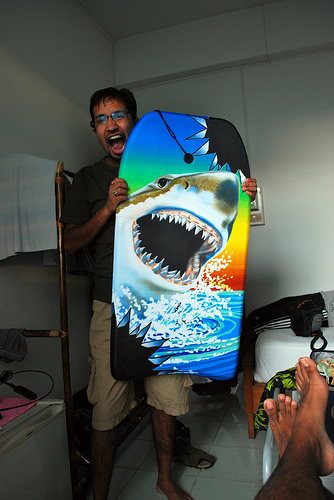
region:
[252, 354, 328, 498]
mans feet on the bed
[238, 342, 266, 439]
a brown bed post under the bed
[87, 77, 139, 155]
a man with glasses on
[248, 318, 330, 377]
a bed with with sheets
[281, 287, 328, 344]
a camera on the bed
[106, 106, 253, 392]
a board with a shark on it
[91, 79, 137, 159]
a man with his mouth open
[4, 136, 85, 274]
white cloth on the rack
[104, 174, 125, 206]
a man with a ring on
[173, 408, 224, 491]
brown sandals on the white floor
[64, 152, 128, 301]
the man is wearing a short sleeve shirt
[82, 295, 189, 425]
the man is wearing shorts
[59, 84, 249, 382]
the man is holding a surfboard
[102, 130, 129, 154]
the man has his mouth open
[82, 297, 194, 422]
the shorts are khaki in color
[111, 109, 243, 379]
the surfboard has a shark painted on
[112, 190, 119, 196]
the man is wearing a ring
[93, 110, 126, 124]
the man is wearing glasses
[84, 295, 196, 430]
the pants are cargo shorts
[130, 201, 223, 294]
the shark has his mouth opened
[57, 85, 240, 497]
a man holding a surfboard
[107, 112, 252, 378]
a surfboard with a shark image on it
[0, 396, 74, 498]
a white mini refrigerator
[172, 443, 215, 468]
a man's strappy sandal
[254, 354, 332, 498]
a man's crossed bare feet and lower legs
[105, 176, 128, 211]
a man's right hand wearing a ring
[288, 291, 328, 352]
a black and gray carrying case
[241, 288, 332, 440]
a bed with mattress and pillows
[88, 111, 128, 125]
a pair of eyeglasses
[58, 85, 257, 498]
a man who is excited to show off his surfboard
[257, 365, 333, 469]
Two barefoot feet that are crossed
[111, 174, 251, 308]
A shark decal on the surfboard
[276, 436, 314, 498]
The man's legs are hairy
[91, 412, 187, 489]
The standing man has hairy legs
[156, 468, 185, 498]
The standing man is barefoot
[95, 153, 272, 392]
The man is holding a small surfboard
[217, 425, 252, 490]
A grey tile floor beneath the men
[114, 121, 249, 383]
A small surfboard in the man's hands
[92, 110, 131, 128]
Glasses on the man's face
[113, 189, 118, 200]
A large ring on the man's finger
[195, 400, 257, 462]
A shadow on the grey tile floor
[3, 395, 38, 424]
A pink towel on the mini fridge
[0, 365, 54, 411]
A thin black wire on the pink towel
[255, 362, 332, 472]
Two hairy, crossed barefoot feet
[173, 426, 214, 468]
The shoes of the man with the surfboard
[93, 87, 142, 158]
The man looks very excited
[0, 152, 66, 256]
A white towel draping from a pole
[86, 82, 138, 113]
The man's hair is black and short